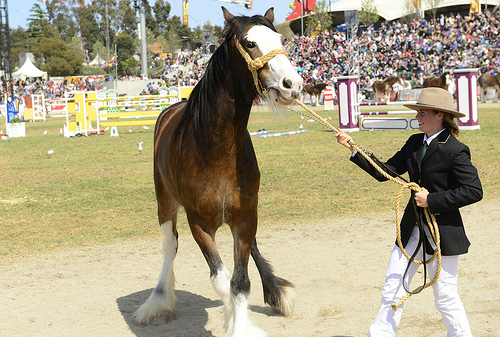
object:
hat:
[401, 86, 464, 120]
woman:
[330, 85, 490, 337]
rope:
[287, 98, 445, 311]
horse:
[130, 7, 306, 337]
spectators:
[0, 14, 500, 120]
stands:
[291, 9, 482, 92]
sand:
[0, 212, 500, 337]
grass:
[0, 103, 499, 262]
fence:
[337, 78, 361, 133]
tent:
[13, 53, 46, 79]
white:
[238, 18, 303, 96]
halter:
[233, 33, 301, 104]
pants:
[364, 229, 469, 337]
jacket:
[348, 132, 482, 255]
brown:
[154, 104, 260, 220]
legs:
[131, 219, 294, 337]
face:
[219, 7, 307, 105]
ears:
[221, 6, 277, 39]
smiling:
[416, 118, 436, 134]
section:
[401, 103, 467, 122]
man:
[391, 68, 400, 72]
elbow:
[401, 62, 409, 69]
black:
[437, 132, 451, 144]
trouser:
[446, 311, 469, 333]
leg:
[128, 212, 176, 327]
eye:
[245, 40, 256, 48]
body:
[187, 138, 264, 222]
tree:
[38, 26, 85, 68]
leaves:
[45, 42, 76, 68]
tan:
[403, 87, 463, 115]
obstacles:
[62, 90, 195, 137]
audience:
[307, 21, 483, 65]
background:
[0, 0, 500, 74]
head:
[210, 5, 304, 107]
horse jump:
[69, 88, 201, 136]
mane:
[190, 59, 260, 122]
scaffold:
[398, 8, 495, 25]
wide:
[399, 101, 466, 121]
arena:
[0, 143, 151, 241]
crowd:
[0, 0, 500, 115]